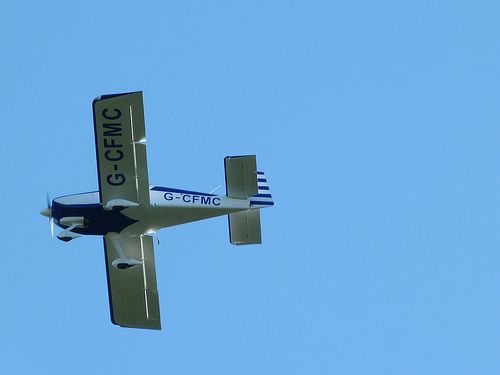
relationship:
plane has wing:
[32, 83, 277, 333] [92, 88, 152, 194]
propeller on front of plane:
[43, 191, 56, 238] [32, 83, 277, 333]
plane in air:
[40, 91, 276, 330] [290, 95, 454, 317]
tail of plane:
[222, 151, 275, 244] [32, 83, 277, 333]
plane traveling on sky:
[32, 83, 277, 333] [1, 0, 496, 371]